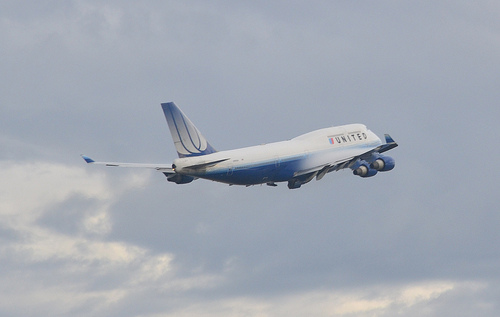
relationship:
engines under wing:
[349, 146, 438, 202] [363, 136, 427, 181]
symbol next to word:
[312, 130, 342, 157] [327, 123, 389, 152]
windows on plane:
[318, 130, 391, 160] [120, 76, 441, 221]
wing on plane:
[313, 133, 379, 178] [71, 96, 421, 203]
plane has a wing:
[71, 96, 421, 203] [313, 133, 379, 178]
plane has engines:
[79, 100, 397, 189] [353, 158, 397, 179]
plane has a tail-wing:
[71, 96, 421, 203] [187, 154, 233, 179]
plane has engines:
[71, 96, 421, 203] [165, 170, 190, 185]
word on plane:
[327, 129, 375, 146] [71, 96, 421, 203]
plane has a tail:
[79, 100, 397, 189] [159, 95, 221, 181]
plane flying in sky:
[79, 100, 397, 189] [28, 20, 478, 303]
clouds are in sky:
[12, 156, 64, 246] [26, 37, 77, 299]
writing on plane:
[324, 130, 376, 146] [79, 100, 397, 189]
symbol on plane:
[322, 134, 338, 152] [79, 100, 397, 189]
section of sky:
[348, 215, 463, 255] [8, 4, 498, 307]